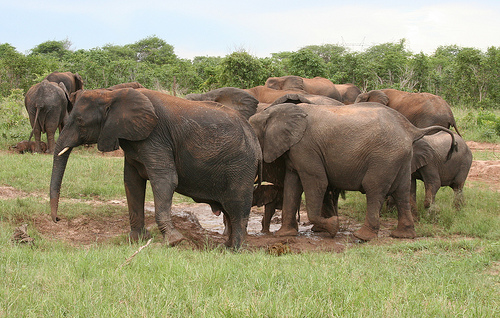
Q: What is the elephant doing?
A: Standing.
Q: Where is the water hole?
A: In grassy field.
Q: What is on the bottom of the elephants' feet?
A: Mud.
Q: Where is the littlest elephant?
A: To the right side.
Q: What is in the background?
A: Trees.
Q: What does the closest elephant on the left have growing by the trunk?
A: Tusks.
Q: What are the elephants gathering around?
A: A watering hole.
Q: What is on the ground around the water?
A: Mud.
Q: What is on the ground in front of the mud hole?
A: Grass.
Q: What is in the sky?
A: Clouds.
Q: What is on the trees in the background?
A: Green leaves.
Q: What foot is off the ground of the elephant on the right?
A: The elephant's front left.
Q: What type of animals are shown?
A: Elephants.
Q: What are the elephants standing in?
A: Mud.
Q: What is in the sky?
A: Clouds.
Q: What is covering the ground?
A: Grass.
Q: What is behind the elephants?
A: Trees.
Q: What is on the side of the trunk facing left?
A: Tusk.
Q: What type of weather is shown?
A: Partly cloudy.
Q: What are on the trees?
A: Leaves.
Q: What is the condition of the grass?
A: Tall.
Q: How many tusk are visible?
A: 1.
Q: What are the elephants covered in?
A: Mud.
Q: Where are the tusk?
A: On the elephants.